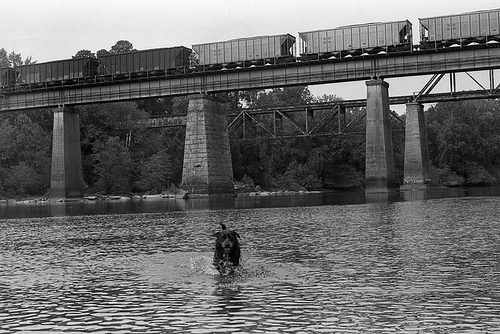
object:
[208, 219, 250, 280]
dog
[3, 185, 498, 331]
water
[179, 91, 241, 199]
pillar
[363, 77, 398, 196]
pillar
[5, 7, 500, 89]
train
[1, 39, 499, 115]
bridge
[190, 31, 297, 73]
car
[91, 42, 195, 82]
car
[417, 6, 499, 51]
car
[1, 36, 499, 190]
vegetation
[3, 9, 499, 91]
track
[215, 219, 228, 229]
tail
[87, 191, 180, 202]
rocks